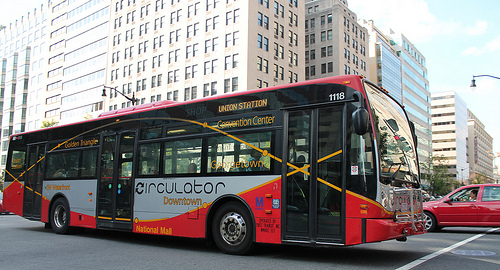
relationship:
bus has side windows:
[0, 74, 427, 253] [10, 127, 284, 181]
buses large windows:
[0, 74, 427, 253] [203, 126, 279, 177]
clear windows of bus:
[203, 126, 279, 177] [0, 74, 427, 253]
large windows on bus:
[203, 126, 279, 177] [0, 74, 427, 253]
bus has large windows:
[0, 74, 427, 253] [203, 126, 279, 177]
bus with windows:
[0, 74, 427, 253] [203, 126, 279, 177]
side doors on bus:
[283, 105, 346, 245] [0, 74, 427, 253]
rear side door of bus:
[25, 138, 45, 217] [0, 74, 427, 253]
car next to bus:
[423, 182, 497, 231] [0, 74, 427, 253]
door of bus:
[283, 105, 346, 245] [0, 74, 427, 253]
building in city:
[428, 88, 493, 184] [1, 1, 498, 270]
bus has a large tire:
[0, 74, 427, 253] [211, 198, 255, 256]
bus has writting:
[0, 74, 427, 253] [135, 180, 225, 209]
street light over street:
[469, 70, 499, 91] [425, 230, 498, 269]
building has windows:
[109, 1, 307, 80] [257, 12, 272, 32]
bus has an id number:
[0, 74, 427, 253] [329, 89, 346, 103]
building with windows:
[109, 1, 307, 80] [257, 12, 272, 32]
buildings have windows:
[305, 1, 369, 77] [319, 12, 333, 27]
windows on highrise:
[319, 12, 333, 27] [305, 1, 369, 77]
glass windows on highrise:
[375, 45, 427, 88] [404, 33, 435, 200]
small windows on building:
[257, 12, 272, 32] [248, 1, 371, 77]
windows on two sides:
[257, 12, 272, 32] [109, 1, 307, 80]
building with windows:
[248, 1, 371, 77] [257, 12, 272, 32]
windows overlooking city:
[431, 92, 457, 163] [1, 1, 498, 270]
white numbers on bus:
[329, 89, 346, 103] [0, 74, 427, 253]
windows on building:
[24, 45, 32, 64] [2, 26, 99, 118]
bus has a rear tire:
[0, 74, 427, 253] [49, 196, 71, 232]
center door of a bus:
[98, 128, 136, 226] [0, 74, 427, 253]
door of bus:
[25, 138, 45, 217] [0, 74, 427, 253]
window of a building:
[259, 33, 265, 48] [377, 40, 401, 93]